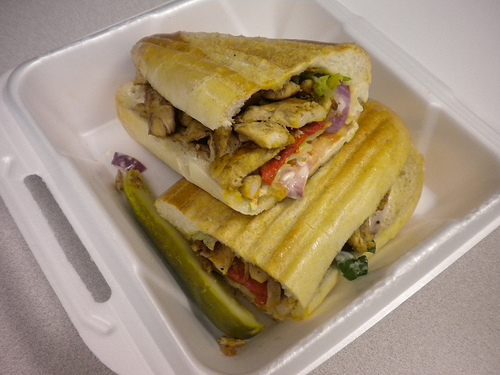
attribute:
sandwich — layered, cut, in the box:
[114, 32, 368, 214]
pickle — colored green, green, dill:
[117, 167, 264, 350]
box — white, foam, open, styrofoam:
[33, 5, 498, 374]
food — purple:
[323, 83, 349, 136]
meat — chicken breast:
[242, 96, 327, 147]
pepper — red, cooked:
[255, 113, 325, 182]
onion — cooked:
[279, 84, 355, 196]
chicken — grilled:
[241, 85, 326, 145]